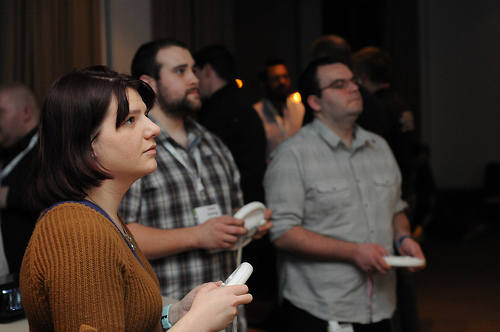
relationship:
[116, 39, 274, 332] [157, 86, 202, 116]
guy has beard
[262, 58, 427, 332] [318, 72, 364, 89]
guy wearing glasses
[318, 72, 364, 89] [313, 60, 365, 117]
glasses on face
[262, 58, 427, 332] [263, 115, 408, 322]
guy wearing shirt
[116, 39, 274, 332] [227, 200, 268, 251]
guy holding remote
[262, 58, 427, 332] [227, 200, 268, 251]
guy with remote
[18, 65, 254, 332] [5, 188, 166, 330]
people wearing sweater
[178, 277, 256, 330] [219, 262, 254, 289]
hands holding controller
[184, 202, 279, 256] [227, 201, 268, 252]
hands holding game control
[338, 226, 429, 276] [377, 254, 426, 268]
hands holding controller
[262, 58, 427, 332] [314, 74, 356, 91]
guy wearing glasses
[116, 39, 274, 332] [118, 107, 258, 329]
guy in  a shirt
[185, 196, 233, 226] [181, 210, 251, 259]
name badge covered by a hand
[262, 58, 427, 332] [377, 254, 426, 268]
guy standing with a controller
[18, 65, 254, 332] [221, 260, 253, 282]
people standing holding a remote controller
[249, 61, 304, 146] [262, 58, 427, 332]
onlooker watching guy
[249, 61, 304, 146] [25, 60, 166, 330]
onlooker watching people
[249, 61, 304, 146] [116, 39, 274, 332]
onlooker watching guy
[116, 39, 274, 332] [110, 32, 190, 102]
guy with hair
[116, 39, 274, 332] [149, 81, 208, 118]
guy with beard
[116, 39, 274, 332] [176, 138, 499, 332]
guy playing a game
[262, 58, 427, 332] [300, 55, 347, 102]
guy with hair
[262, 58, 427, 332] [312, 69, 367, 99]
guy with glasses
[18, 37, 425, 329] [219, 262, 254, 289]
three people with controller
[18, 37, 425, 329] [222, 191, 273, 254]
three people with game control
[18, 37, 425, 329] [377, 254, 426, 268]
three people with controller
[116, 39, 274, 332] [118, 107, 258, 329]
guy in shirt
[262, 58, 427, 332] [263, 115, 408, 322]
guy with shirt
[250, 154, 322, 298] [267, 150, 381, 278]
sleeve on arm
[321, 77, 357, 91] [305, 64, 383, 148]
glasses on face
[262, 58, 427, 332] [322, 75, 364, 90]
guy has glasses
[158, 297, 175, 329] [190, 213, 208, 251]
watch on wrist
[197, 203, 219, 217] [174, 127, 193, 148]
key tag on chest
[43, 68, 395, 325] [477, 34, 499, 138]
people playing game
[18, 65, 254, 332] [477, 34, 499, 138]
people playing game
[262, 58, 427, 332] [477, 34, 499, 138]
guy playing game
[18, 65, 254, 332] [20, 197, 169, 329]
people on shirt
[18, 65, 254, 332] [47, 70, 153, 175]
people has dark hair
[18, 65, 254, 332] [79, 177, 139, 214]
people wearing necklace around neck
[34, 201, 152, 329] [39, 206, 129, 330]
sweater has sleeve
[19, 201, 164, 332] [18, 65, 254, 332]
sweater on people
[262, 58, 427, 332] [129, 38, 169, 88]
guy has hair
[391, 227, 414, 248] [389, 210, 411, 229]
watch on wrist